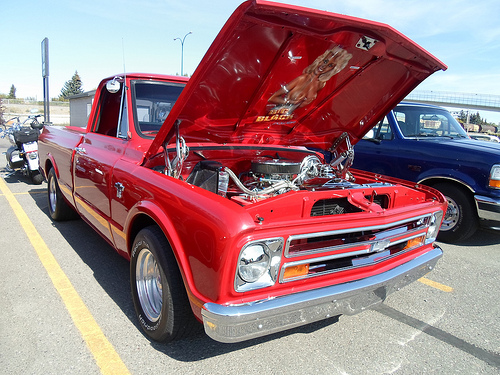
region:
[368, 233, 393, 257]
the logo is silver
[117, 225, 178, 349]
the tire is black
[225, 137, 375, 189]
the engine is silver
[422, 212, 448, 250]
the car has a headlamp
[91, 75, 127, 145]
the window is open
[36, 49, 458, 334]
the car is red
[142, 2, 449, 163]
hood of red truck in upright position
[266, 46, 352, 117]
artwork of partially naked woman under truck hood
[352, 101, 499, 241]
blue truck parked beside red truck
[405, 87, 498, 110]
overpass in distance behind blue truck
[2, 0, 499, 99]
light blue but cloudy sky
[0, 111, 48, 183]
motorcycle parked behind shiny red truck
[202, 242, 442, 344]
silver chrome bumper on shiny red truck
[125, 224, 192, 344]
front passenger side tire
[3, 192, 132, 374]
yellow line painted on parking lot of passenger side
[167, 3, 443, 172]
The hood of the red pickup truck.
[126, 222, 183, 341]
The front tire of the red truck.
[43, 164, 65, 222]
The back tire of the truck.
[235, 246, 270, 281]
The left headlight of the red truck.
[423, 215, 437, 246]
The right headlight of the red truck.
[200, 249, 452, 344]
The front fender of the red truck.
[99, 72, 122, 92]
The side view mirror on the red truck.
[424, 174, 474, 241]
The front wheel of the blue truck.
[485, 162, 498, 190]
The headlight of the blue truck.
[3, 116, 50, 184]
The motorcycle behind the red truck.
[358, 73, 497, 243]
the car is blue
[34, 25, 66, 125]
this is a pole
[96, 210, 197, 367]
this is a wheel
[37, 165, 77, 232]
this is a wheel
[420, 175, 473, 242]
this is a wheel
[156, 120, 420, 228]
the bonnet is open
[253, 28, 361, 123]
a picture in the bonet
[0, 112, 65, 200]
this is a motorbike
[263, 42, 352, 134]
The woman drawing under the hood.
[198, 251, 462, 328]
The silver front bumper.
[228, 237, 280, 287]
The left headlight on the car.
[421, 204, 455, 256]
The right headlight on the car.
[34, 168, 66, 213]
The left back tire.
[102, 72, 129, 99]
The rear view mirror above the window.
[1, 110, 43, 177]
The motorcycle behind the truck.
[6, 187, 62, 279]
The yellow line in the pavement.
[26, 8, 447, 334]
the car is red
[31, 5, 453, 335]
this is a car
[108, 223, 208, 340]
this is a tire